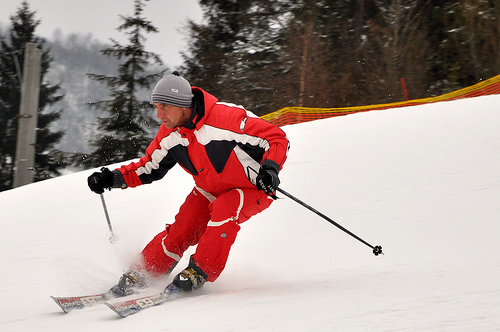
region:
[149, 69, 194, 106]
gray winter hat on a man's head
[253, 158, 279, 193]
black and gray left winter glove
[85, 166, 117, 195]
right hand winter glove that is black and gray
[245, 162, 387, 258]
black left handed ski pole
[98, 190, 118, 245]
man hanging on to a black pole for skiing in his right hand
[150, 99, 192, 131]
white man's face who is in extreme concentration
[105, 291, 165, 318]
red white and blue ski for the left foot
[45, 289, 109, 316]
ski for the right side that is blue white and red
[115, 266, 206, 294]
black boots used for skiing on the snow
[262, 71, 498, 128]
orange and yellow fence to mark boundaries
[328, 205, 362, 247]
part of a hooker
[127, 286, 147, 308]
part of a board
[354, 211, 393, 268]
part of a hooker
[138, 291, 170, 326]
part of a board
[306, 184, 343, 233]
part of a hooker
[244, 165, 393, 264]
black glove and ski pole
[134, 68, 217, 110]
gray hat on head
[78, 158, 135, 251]
right glove and ski pole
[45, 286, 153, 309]
right ski on skier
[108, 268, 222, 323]
left ski on skier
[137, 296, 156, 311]
number 83 on ski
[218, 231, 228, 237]
name brand patch on ski pants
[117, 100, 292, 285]
red, white and black ski pants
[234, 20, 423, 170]
orange and yellow fence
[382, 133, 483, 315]
snow on the ground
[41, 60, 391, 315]
man in the snow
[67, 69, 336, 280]
red and white jacket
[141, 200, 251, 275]
legs of the man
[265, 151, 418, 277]
pole in person's hand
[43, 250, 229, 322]
skis on the ground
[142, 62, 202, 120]
hat on man's head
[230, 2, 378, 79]
trees in the distance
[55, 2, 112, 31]
sky above the trees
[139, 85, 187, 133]
face of the man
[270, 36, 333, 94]
branch on the tree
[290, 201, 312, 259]
part of a hooker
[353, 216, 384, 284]
part fo a hooker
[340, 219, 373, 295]
part of a hooker